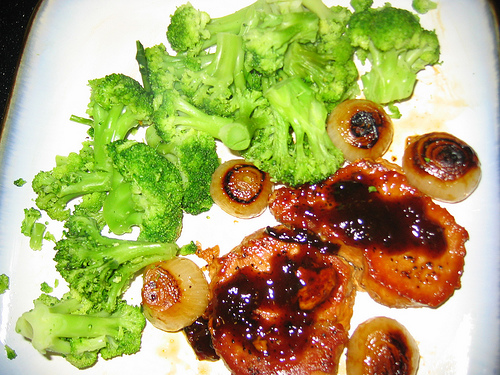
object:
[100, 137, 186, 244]
broccoli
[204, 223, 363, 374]
fillets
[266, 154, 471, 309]
fillets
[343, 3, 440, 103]
broccoli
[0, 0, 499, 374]
plate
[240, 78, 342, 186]
vegetable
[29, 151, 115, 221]
vegitable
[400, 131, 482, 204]
onion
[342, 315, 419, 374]
onion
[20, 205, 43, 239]
broccoli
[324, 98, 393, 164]
food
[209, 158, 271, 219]
food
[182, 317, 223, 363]
sauce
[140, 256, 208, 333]
cooked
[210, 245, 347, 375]
sauce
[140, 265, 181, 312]
ring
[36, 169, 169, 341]
top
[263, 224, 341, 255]
black